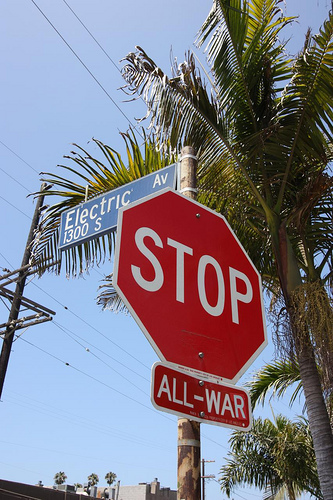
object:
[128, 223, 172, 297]
s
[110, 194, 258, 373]
sign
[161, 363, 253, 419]
sign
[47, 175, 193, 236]
sign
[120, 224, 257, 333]
stop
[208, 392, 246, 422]
war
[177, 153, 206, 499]
pole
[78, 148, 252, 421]
signs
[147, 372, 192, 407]
all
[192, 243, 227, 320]
o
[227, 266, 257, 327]
p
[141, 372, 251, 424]
message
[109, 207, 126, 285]
border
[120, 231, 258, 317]
lettering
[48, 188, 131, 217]
electric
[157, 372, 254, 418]
all war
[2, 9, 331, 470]
background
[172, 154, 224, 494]
sign post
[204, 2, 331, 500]
tree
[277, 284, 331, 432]
trunk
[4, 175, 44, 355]
post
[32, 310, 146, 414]
cables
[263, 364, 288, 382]
leaf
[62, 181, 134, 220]
name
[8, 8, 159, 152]
sky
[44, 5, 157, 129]
wires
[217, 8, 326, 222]
leaves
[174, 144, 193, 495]
post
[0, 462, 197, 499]
buildings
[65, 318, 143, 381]
power lines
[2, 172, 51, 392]
pole